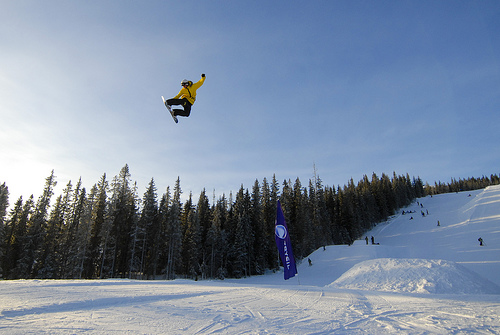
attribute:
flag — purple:
[270, 198, 299, 281]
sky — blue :
[0, 0, 498, 221]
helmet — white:
[149, 73, 203, 87]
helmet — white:
[177, 77, 189, 83]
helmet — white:
[178, 77, 192, 85]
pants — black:
[165, 97, 191, 115]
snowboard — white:
[166, 68, 209, 121]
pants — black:
[165, 96, 192, 121]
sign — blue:
[268, 194, 303, 281]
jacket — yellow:
[169, 74, 208, 104]